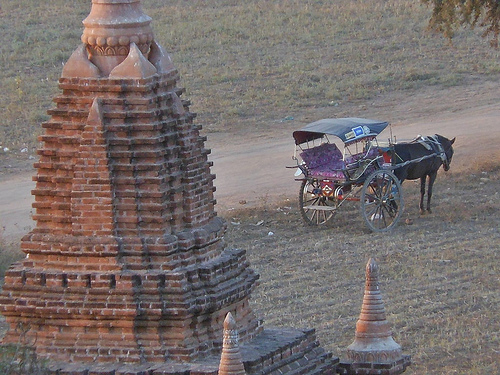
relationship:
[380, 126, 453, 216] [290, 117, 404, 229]
horse pulling cart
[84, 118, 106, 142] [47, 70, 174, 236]
brick attached to wall